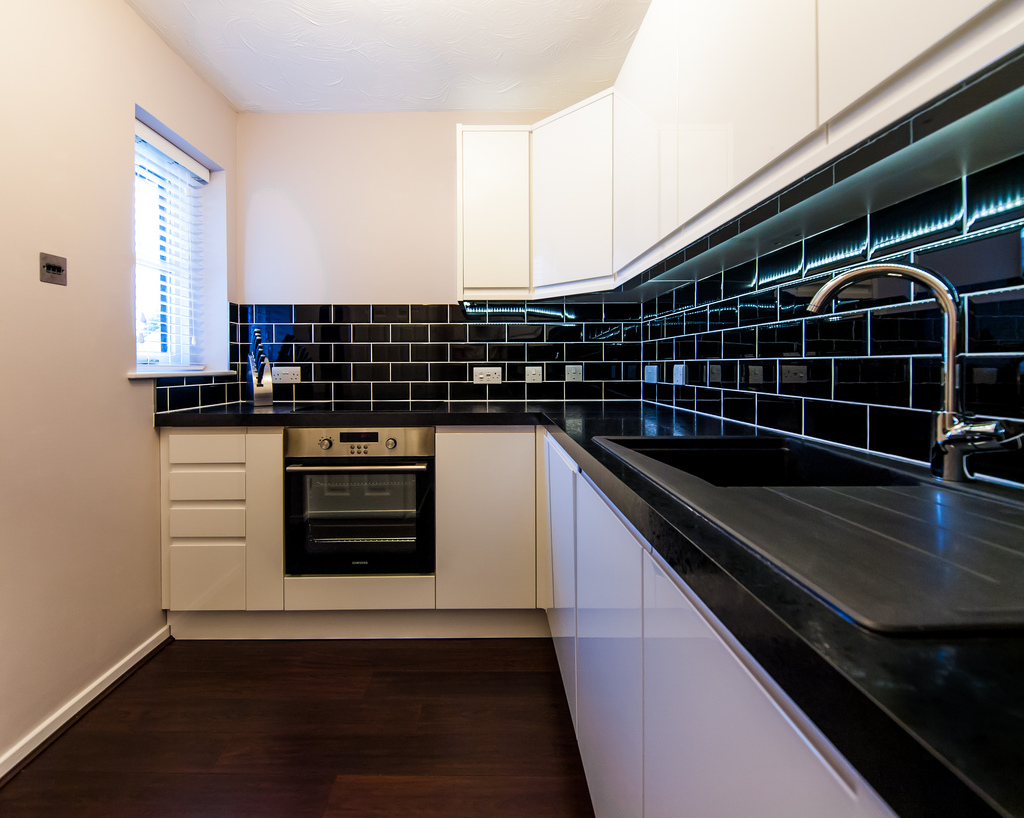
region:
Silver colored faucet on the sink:
[798, 250, 1002, 473]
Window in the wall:
[128, 98, 236, 380]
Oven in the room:
[280, 411, 442, 583]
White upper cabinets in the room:
[435, 4, 1021, 312]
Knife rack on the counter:
[231, 322, 280, 414]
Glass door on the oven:
[298, 467, 423, 535]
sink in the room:
[610, 418, 927, 504]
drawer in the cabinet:
[160, 429, 255, 469]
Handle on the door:
[277, 456, 432, 477]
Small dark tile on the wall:
[287, 302, 338, 323]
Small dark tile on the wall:
[364, 302, 412, 328]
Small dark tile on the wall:
[405, 302, 454, 328]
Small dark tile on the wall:
[505, 324, 544, 343]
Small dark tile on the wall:
[448, 337, 493, 361]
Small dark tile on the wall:
[945, 346, 1022, 405]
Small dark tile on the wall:
[711, 390, 766, 432]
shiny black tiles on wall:
[231, 296, 644, 411]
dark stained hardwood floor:
[4, 635, 597, 816]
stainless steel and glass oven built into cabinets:
[280, 420, 436, 575]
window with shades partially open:
[131, 111, 214, 375]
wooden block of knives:
[242, 322, 278, 409]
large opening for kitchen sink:
[611, 420, 921, 494]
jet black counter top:
[172, 397, 758, 435]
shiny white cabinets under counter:
[531, 427, 892, 813]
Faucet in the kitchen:
[771, 240, 1006, 485]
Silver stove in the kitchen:
[261, 414, 458, 585]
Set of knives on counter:
[240, 326, 288, 399]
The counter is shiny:
[170, 380, 690, 453]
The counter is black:
[187, 380, 669, 428]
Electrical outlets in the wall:
[262, 345, 599, 399]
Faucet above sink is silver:
[776, 255, 1007, 496]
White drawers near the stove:
[166, 436, 290, 608]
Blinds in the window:
[116, 124, 241, 372]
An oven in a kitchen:
[277, 427, 436, 568]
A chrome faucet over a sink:
[808, 266, 967, 482]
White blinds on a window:
[130, 154, 200, 369]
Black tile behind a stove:
[149, 307, 647, 412]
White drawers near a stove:
[163, 423, 246, 616]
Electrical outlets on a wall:
[466, 360, 591, 387]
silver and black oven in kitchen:
[280, 423, 448, 588]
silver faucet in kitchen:
[812, 252, 1002, 480]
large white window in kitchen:
[123, 118, 232, 388]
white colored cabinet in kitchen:
[455, 116, 531, 300]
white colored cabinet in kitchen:
[539, 107, 609, 282]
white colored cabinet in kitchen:
[439, 429, 535, 619]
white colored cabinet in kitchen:
[534, 441, 582, 637]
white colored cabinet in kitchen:
[571, 483, 635, 798]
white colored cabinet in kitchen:
[597, 72, 683, 234]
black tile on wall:
[246, 305, 295, 326]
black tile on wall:
[272, 323, 311, 340]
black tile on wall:
[167, 387, 203, 406]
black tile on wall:
[867, 404, 937, 462]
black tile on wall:
[800, 396, 868, 444]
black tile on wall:
[753, 396, 807, 429]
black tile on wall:
[600, 380, 642, 401]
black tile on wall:
[563, 378, 605, 398]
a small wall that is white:
[236, 86, 458, 308]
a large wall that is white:
[5, 4, 265, 679]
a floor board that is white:
[26, 674, 116, 735]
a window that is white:
[102, 154, 230, 367]